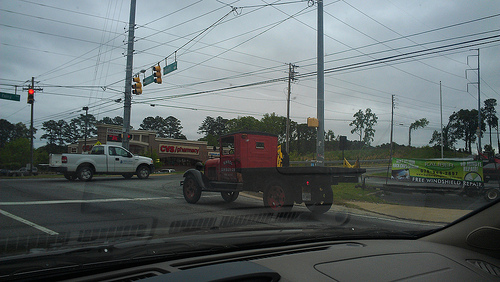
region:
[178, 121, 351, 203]
this is a truck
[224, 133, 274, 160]
the truck is red in color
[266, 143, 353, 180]
the back is empty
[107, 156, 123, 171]
the truck is parked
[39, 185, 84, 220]
this is the road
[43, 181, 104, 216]
the road is tarmacked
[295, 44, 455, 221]
this is the front screen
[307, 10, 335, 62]
this is a pole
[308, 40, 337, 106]
the pole is long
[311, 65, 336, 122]
the pole is straight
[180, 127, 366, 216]
an antique flat bed truck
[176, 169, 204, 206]
the wheel of an antique flatbed truck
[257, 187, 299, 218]
the back wheels of an antique flatbed truck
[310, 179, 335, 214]
the back wheels of an antique flatbed truck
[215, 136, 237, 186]
the door of an antique truck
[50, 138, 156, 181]
a white pick up truck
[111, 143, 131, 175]
the door of a pickup truck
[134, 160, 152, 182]
the wheel of a pickup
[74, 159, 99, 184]
the wheel of a pickup truck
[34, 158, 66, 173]
the tailgate of a pickup truck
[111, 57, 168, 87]
The street lights are yellow.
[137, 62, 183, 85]
The street signs are green.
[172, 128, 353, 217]
The truck is red.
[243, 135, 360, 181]
The truck bed is empty.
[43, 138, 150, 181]
The truck is white.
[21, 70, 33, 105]
The light is red.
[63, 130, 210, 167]
The building is tan.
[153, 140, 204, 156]
The lettering is red.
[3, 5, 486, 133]
The sky is cloudy.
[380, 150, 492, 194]
The sign is next to the road.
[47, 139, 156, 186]
truck on the road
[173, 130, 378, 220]
truck on the road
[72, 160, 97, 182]
tire on a truck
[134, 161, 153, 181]
tire on a truck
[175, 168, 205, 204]
tire on a truck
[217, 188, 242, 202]
tire on a truck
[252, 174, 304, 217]
tire on a truck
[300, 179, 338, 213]
tire on a truck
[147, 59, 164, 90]
traffic light hanging over road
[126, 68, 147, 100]
traffic light hanging over road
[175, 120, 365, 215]
An antique red truck.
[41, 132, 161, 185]
A white truck in the intersections.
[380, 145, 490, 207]
A banner on the side of the road.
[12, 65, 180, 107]
Traffic lights at an intersecton.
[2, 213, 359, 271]
Windshield wiper blades at rest.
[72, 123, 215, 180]
A pharmacy at the intersection.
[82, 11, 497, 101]
Multiple utility lines on metal poles.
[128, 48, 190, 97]
Traffic lights and street signs.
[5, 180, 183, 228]
White lines on the road.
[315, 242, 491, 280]
An airbag in the car.